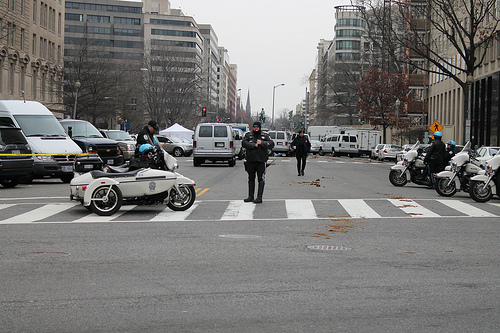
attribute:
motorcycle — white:
[68, 130, 197, 216]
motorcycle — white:
[435, 129, 500, 206]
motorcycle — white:
[387, 138, 457, 186]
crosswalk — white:
[1, 199, 497, 226]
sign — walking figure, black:
[429, 120, 444, 138]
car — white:
[378, 143, 404, 163]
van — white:
[190, 122, 239, 168]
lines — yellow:
[192, 184, 209, 200]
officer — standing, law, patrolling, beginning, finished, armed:
[237, 121, 276, 206]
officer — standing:
[133, 118, 164, 209]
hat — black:
[147, 119, 159, 131]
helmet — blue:
[434, 130, 443, 139]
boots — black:
[242, 179, 254, 202]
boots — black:
[252, 178, 267, 207]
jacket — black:
[240, 130, 274, 164]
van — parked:
[1, 94, 86, 185]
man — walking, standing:
[292, 129, 313, 177]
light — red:
[199, 106, 206, 120]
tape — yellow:
[1, 150, 101, 160]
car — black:
[1, 123, 36, 190]